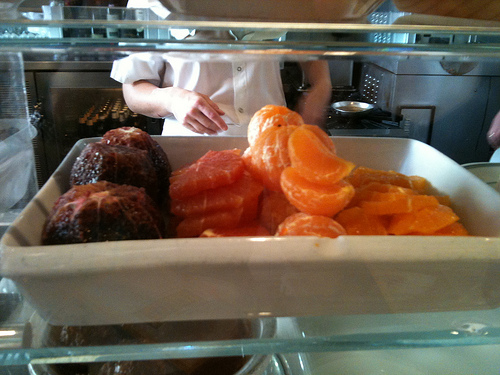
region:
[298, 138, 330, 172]
orange wedge in the pan.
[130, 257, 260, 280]
plastic pan on shelf.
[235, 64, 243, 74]
button on the shirt.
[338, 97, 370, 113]
pan on the stove.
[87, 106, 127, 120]
bottles near the stove.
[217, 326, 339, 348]
shelf made of glass.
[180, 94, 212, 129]
person's right hand.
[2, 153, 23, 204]
white plastic bag in background.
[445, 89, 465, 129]
commercial stainless steel kitchen appliance.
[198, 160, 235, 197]
slices of grapefruit in pan.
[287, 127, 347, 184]
a slice of orange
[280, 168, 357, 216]
a slice of orange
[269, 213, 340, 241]
a slice of orange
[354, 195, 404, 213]
a slice of orange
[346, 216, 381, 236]
a slice of orange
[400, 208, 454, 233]
a slice of orange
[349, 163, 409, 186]
a slice of orange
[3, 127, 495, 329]
a white baking tray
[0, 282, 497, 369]
a clear glass shelf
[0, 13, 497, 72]
a clear glass shelf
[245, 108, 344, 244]
Peeled oranges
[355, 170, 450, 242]
A pile of orange slices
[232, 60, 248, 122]
Buttons on the white chefjacket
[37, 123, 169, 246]
A dark fruit in the tub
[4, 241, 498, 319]
A glass white tub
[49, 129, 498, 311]
A tub with fruit in it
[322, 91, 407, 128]
A pan on the stove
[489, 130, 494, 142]
A ring on the blurry hand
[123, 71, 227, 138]
The arm of the chef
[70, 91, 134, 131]
Bottles in a fridge on the ground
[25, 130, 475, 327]
white tray with peeled fruit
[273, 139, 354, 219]
oranges with no skin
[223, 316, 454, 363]
glass edge of shelf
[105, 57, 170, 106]
rolled up white sleeve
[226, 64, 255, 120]
buttons on white shirt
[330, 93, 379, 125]
shiny round metal pan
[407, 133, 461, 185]
light reflection on tray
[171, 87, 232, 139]
hand in front of shirt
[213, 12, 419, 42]
edge of glass top shelf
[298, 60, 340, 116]
blur of moving arm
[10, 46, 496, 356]
a container of fruit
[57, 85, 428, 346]
a container of peeled fruti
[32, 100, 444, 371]
a container with fruit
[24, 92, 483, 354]
a container with peeled fruit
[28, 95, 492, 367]
a container with food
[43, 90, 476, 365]
a white container with fruit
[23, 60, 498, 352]
a white container with peeled fruit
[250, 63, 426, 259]
orange slices in a pile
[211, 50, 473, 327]
peeled orange slices together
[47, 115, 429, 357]
a container of food on shelf